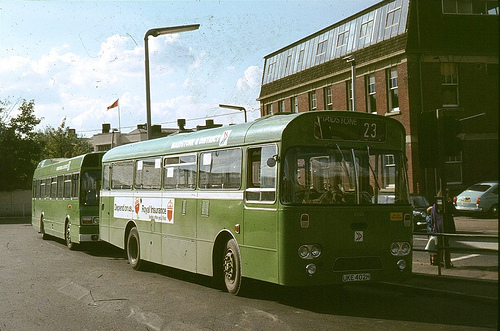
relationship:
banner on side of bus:
[108, 198, 181, 224] [101, 110, 416, 297]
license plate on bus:
[340, 269, 375, 290] [101, 110, 416, 297]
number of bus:
[361, 119, 380, 141] [101, 112, 413, 250]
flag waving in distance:
[105, 95, 122, 114] [71, 49, 134, 72]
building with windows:
[259, 0, 498, 117] [366, 68, 413, 118]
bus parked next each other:
[32, 151, 104, 249] [68, 144, 116, 265]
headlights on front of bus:
[299, 239, 415, 259] [101, 112, 413, 250]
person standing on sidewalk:
[425, 179, 463, 265] [455, 257, 497, 307]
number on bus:
[361, 119, 380, 141] [101, 112, 413, 250]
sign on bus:
[108, 198, 181, 224] [101, 112, 413, 250]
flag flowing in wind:
[105, 95, 122, 114] [92, 93, 131, 97]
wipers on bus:
[336, 138, 357, 193] [101, 112, 413, 250]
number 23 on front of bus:
[361, 119, 380, 141] [101, 112, 413, 250]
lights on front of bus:
[291, 237, 323, 284] [101, 112, 413, 250]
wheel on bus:
[218, 238, 243, 295] [101, 112, 413, 250]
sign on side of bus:
[108, 198, 181, 224] [101, 112, 413, 250]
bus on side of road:
[101, 112, 413, 250] [92, 268, 157, 325]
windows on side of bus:
[244, 144, 266, 190] [101, 112, 413, 250]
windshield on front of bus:
[280, 141, 413, 207] [101, 112, 413, 250]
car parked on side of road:
[412, 188, 438, 231] [459, 220, 489, 257]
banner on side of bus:
[108, 198, 181, 224] [101, 112, 413, 250]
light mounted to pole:
[146, 18, 203, 43] [142, 27, 153, 138]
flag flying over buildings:
[105, 95, 122, 114] [80, 114, 247, 150]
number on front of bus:
[361, 119, 380, 141] [101, 112, 413, 250]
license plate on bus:
[340, 269, 375, 290] [101, 112, 413, 250]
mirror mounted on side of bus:
[265, 153, 283, 169] [101, 112, 413, 250]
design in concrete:
[51, 275, 239, 330] [30, 256, 72, 272]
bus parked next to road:
[32, 151, 104, 249] [92, 268, 157, 325]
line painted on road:
[445, 242, 483, 273] [459, 220, 489, 257]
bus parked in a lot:
[101, 112, 413, 250] [10, 288, 490, 327]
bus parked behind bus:
[101, 112, 413, 250] [25, 151, 97, 249]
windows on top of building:
[366, 68, 413, 118] [259, 0, 498, 117]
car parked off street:
[453, 175, 499, 219] [459, 214, 484, 230]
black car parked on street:
[412, 188, 438, 231] [459, 214, 484, 230]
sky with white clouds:
[6, 5, 139, 55] [57, 53, 137, 113]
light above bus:
[146, 18, 203, 43] [101, 112, 413, 250]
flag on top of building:
[105, 95, 122, 114] [81, 118, 213, 141]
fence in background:
[2, 185, 31, 221] [6, 86, 36, 154]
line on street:
[445, 242, 483, 273] [459, 214, 484, 230]